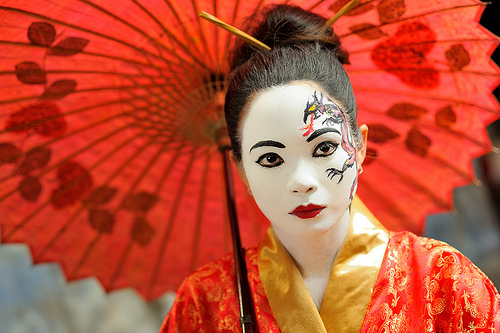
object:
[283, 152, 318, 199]
nose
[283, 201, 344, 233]
lips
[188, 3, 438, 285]
woman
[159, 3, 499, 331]
woman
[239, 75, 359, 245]
face makeup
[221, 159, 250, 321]
pole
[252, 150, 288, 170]
eye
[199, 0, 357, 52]
chopsticks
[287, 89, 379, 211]
dragon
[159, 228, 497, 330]
red outfit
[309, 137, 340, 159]
eye.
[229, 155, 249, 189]
left ear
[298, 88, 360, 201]
image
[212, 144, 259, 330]
handle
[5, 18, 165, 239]
decorations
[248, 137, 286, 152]
eyebrow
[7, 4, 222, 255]
umbrella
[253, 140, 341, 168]
eyes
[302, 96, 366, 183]
dragon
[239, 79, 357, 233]
face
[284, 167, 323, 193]
nose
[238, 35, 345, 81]
hair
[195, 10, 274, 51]
stick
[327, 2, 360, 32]
stick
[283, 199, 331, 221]
lips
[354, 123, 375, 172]
ear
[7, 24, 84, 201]
flower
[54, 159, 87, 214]
flower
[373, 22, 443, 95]
flower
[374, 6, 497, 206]
umbrella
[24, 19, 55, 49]
leaf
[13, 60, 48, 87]
leaf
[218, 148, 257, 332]
handle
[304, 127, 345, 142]
eyebrow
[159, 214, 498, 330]
kimono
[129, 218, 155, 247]
leaf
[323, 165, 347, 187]
claw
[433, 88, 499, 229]
edge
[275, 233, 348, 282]
neck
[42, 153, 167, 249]
leaves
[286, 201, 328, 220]
lipstick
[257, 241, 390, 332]
collar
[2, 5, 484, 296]
umbrella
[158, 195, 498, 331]
robe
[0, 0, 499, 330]
umbrella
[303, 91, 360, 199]
dragon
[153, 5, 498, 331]
girl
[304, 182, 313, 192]
nostril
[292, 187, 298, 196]
nostril